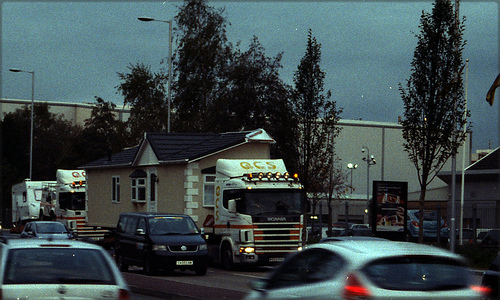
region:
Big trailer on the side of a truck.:
[186, 131, 228, 212]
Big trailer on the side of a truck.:
[12, 87, 59, 249]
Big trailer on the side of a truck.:
[217, 103, 493, 151]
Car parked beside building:
[111, 193, 224, 286]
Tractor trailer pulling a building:
[128, 109, 342, 299]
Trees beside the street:
[148, 25, 430, 228]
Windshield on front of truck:
[212, 174, 307, 255]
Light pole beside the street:
[9, 47, 45, 132]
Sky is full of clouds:
[340, 18, 400, 67]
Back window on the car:
[360, 246, 496, 296]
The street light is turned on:
[339, 150, 368, 202]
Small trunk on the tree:
[402, 143, 442, 239]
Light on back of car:
[34, 238, 80, 258]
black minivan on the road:
[109, 211, 207, 278]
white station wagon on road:
[1, 237, 125, 299]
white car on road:
[249, 237, 485, 299]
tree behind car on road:
[395, 0, 475, 240]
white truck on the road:
[216, 159, 308, 270]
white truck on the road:
[57, 169, 92, 233]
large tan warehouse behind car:
[0, 96, 474, 241]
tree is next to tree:
[296, 29, 358, 221]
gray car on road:
[19, 217, 74, 237]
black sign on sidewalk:
[374, 182, 407, 240]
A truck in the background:
[79, 120, 313, 270]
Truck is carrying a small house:
[75, 113, 313, 270]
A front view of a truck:
[208, 151, 319, 270]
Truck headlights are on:
[234, 239, 313, 261]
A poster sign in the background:
[364, 172, 414, 247]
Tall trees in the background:
[0, 1, 475, 238]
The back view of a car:
[245, 235, 492, 297]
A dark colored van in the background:
[108, 203, 215, 283]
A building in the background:
[3, 83, 478, 242]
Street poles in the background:
[3, 12, 185, 178]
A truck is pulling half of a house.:
[86, 125, 304, 265]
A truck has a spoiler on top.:
[51, 165, 89, 238]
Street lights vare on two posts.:
[346, 143, 372, 201]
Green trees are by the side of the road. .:
[0, 2, 468, 239]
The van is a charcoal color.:
[112, 210, 203, 270]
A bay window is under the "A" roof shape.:
[125, 130, 151, 205]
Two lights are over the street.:
[5, 15, 170, 180]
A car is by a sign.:
[375, 180, 450, 235]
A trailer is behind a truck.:
[5, 175, 50, 220]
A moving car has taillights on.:
[253, 241, 489, 297]